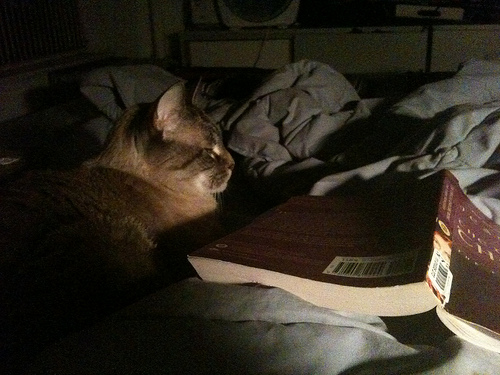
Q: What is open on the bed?
A: A book.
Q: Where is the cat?
A: Next to book.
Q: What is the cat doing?
A: Sleeping.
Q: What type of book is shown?
A: Paper.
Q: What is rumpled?
A: The bedspread.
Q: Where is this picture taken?
A: A bedroom.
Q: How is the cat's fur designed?
A: Striped.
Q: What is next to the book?
A: Cat sleeping on a comforter.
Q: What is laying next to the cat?
A: Book.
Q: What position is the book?
A: Open.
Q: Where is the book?
A: On the bed.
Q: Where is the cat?
A: On the bed.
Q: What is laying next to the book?
A: Cat.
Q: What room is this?
A: Bedroom.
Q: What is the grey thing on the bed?
A: Comforter.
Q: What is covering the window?
A: Blinds.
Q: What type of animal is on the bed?
A: Cat.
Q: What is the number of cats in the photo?
A: One.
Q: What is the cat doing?
A: Sleeping.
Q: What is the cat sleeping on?
A: Blanket.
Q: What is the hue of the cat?
A: Gray.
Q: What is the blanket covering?
A: Bed.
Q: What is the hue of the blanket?
A: Gray.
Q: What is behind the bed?
A: Wall.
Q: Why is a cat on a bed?
A: To sleep.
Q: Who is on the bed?
A: A cat.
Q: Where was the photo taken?
A: In a bedroom.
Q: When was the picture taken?
A: Night.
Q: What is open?
A: Book.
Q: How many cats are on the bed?
A: One.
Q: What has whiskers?
A: The cat.